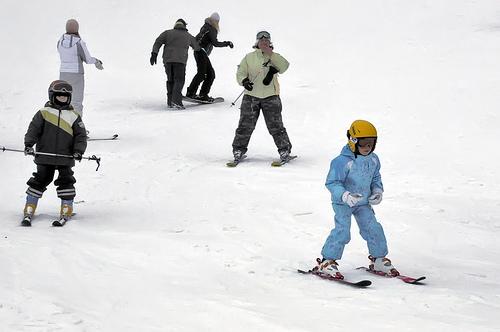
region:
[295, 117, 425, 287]
child dressed in blue on red skis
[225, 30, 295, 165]
skier in light colored jacket wearing black gloves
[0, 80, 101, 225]
child on left holding ski pole with both hands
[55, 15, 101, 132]
woman in white jacket looking toward the right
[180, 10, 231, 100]
snowboarder in dark clothes with white cap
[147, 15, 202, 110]
person in dark clothes directly left of snowboarder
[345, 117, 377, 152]
yellow ski helmet on child in light blue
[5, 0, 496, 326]
snow the people are enjoying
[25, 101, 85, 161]
child's jacket with two colored stripes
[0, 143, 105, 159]
ski pole child on left is holding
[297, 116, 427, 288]
a child skiing downhill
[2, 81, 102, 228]
a child skiing downhill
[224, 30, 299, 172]
a person skiing downhill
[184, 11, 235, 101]
a female snowboarder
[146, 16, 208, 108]
a man walking on snow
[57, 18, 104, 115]
a person standing in snow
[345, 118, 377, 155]
a yellow protective helmet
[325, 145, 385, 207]
a blue snow coat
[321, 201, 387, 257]
a pair of blue snow pants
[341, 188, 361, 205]
a white snow glove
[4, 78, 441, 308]
these kids are skiing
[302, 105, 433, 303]
the girl is wearing a blue snow suit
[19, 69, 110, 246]
the boy is wearing a black snow suit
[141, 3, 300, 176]
three of the six people on the slope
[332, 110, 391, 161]
the girls helmet is yellow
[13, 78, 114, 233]
the boy is young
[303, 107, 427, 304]
the girl is young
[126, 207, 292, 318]
there is snow on the slope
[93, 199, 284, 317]
the snow is white in color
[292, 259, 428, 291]
the young girls ski's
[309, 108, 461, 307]
child wearing snow skis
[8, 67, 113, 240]
child carrying ski pole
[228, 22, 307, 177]
person removed left glove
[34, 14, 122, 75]
person in white jacket with gray trim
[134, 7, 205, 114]
person walking on the snow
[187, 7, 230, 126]
person on snowboard on snow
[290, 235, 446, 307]
red skis and red and white ski boots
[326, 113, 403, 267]
child wearing blue snowsuit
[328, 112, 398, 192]
child wearing yellow/orange helmet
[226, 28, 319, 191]
person wearing camouflage pants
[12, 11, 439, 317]
People skiing in the snow.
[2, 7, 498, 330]
Snow covering the ground.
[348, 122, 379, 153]
A yellow helmet.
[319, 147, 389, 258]
A light blue colored ski outfit.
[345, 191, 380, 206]
White ski gloves.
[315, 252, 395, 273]
White and red ski boots.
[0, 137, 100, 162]
A ski pole.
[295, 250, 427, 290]
A child's pair of skis.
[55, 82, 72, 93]
A pair of ski goggles.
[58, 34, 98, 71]
A white and grey ski coat.